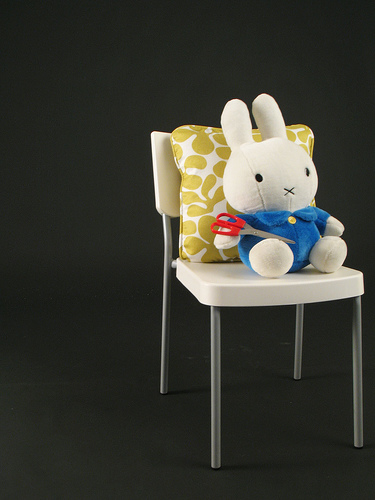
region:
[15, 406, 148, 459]
solid black floor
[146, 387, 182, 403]
edge of gray foot on chair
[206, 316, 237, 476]
long shiny gray chair leg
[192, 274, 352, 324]
white edge of seat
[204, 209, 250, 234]
red handle of scissors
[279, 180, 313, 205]
nose on white teddy bear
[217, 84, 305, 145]
long bunny ears on bear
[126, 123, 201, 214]
white back of chair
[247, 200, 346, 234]
blue bow tie on bear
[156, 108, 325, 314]
gold and white pillow on chair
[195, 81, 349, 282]
Kitty plush is white and blue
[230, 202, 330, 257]
Kitty plush body is blue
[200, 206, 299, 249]
Scissors are red and grey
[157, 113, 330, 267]
Pillow is behind kitty plush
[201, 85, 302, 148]
Ears of plus is white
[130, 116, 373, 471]
Chair is white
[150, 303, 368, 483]
Four legs of chair is grey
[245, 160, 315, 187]
Eyes of plus are black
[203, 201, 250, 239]
Finger holes of scissors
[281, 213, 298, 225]
Yellow button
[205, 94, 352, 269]
a little bunny sitting in the chair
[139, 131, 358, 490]
the chair the bunny is sitting on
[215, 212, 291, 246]
the scissors the bunny is holding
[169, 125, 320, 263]
the pillow behind the bunny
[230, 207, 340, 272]
the blue clothes on the bunny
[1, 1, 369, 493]
the black wall behind the bunny and chair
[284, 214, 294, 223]
the yellow button on the blue outfit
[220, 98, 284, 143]
the ears of the bunny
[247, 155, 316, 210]
the face of the bunny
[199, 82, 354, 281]
Plush is white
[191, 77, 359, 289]
Plush is a cat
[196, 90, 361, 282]
Body of plush is blue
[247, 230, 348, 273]
Legs of plush is white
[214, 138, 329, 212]
Head of plush is white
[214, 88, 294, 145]
Ears of plush is white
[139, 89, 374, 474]
Plush sits on a white chair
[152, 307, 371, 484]
Legs of chair are tan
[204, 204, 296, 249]
Pair of red scissors on plush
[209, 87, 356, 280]
white toy rabbit on chair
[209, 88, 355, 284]
white toy rabbit wearing blue suit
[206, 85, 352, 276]
white toy rabbit with silver and red handled scissors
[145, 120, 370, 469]
white chair with silver metal legs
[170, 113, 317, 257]
white and yellow pillow on chair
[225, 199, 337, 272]
blue suit with yellow button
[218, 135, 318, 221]
white face with black eyes and black mouth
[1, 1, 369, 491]
black room with white chair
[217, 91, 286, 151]
two white upright ears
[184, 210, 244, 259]
yellow flower on white pillow